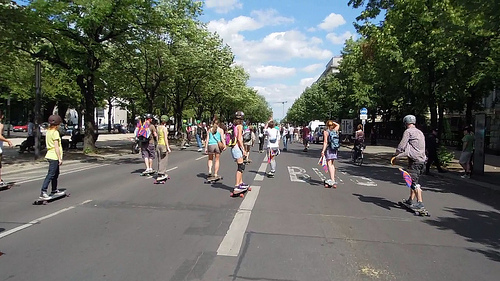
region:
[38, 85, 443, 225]
group of people skate boarding down center of raod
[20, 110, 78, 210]
girl in yellow shirt and blue jeans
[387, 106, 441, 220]
man riding a skateboard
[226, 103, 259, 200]
woman wearing helmet and blue shorts on skateboard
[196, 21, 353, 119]
trees and sky fading into the horizon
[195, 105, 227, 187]
woman riding skateboard wearing green shirt and brown shorts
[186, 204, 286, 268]
white line on street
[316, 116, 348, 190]
woman with back pack riding skateboard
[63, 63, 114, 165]
tree trunk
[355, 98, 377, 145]
street sign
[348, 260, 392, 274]
small white spot on street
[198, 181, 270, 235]
large white line in middle of street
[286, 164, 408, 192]
large words on the street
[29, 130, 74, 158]
woman wearing yellow shirt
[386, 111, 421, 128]
gray cap on man's head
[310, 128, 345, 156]
blue backpack on man's back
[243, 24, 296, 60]
soft fluffy white clouds in the sky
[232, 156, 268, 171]
black knee pads on woman's knee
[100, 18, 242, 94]
cluster of tall green trees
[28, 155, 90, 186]
woman wearing tight black pants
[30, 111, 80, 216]
young person on skateboard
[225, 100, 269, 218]
young person on skateboard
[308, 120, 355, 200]
young person on skateboard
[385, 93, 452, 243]
young person on skateboard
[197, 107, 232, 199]
young person on skateboard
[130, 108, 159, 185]
young person on skateboard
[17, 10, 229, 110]
green leaves on brown trees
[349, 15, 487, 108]
green leaves on brown trees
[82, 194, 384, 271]
gray street with white stripes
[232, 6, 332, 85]
blue sky with white clouds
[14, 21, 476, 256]
Picture is taken during the day.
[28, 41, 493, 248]
The sun is out.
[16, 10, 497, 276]
Picture is taken outside.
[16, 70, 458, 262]
Many people are on the street.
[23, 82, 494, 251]
People are riding skateboards.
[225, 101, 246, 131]
Person is wearing a protective helmet.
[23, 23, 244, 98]
The trees are full of leaves.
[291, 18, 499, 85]
Dark green leaves on the trees.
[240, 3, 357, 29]
The sky is light blue.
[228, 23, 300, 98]
White clouds in the sky.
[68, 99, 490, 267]
the people have helmets on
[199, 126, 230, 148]
the girl has a blue top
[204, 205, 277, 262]
the lines are white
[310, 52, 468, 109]
the trees are green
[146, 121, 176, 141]
she has a yellow top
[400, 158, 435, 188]
the pants are black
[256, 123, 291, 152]
the top is white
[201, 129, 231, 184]
she is wearing shorts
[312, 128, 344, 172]
she has a backpack on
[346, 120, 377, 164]
she is riding a bike